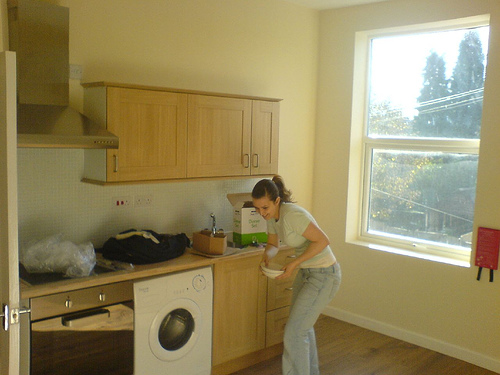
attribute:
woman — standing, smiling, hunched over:
[253, 175, 341, 374]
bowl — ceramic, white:
[261, 264, 285, 279]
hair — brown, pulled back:
[251, 176, 293, 203]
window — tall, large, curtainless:
[359, 25, 490, 261]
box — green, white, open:
[229, 193, 267, 245]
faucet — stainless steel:
[211, 212, 217, 237]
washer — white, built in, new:
[134, 266, 212, 374]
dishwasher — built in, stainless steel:
[29, 279, 134, 374]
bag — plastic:
[23, 234, 96, 278]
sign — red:
[475, 228, 499, 280]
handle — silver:
[114, 155, 118, 172]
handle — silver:
[246, 155, 249, 167]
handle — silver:
[255, 154, 259, 167]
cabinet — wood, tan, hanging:
[81, 82, 187, 185]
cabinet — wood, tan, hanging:
[188, 90, 251, 181]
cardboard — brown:
[193, 230, 228, 254]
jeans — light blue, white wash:
[287, 264, 341, 374]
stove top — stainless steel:
[19, 260, 112, 285]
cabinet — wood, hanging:
[249, 96, 282, 177]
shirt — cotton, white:
[266, 202, 335, 266]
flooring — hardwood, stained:
[223, 311, 498, 374]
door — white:
[0, 51, 21, 374]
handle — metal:
[0, 306, 30, 330]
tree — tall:
[414, 52, 450, 135]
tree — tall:
[450, 32, 484, 138]